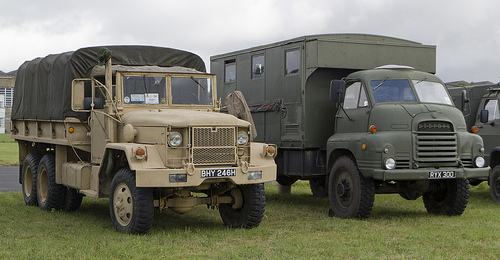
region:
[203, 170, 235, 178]
black and white licence plate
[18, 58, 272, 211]
tan and green army truck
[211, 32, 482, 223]
green metal army truck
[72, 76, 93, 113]
rear view truck mirror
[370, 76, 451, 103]
glass windshield on truck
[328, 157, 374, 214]
black rubber truck tire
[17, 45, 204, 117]
green tarp on truck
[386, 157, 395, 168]
round headlight on truck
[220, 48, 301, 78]
windows on side of truck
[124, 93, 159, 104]
papers in truck window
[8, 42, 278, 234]
large tan vehicle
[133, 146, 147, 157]
orange light on the front of a tan truck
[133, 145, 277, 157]
two orange lights on a tan vehicle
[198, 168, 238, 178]
black and white license plate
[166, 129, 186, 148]
round white light on the front of a tan vehicle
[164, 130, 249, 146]
two white headlights on a tan vehicle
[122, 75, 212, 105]
windshield of a tan truck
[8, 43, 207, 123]
black material covering the back of a truck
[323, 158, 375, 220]
large black wheel on a truck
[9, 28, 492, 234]
two trucks in a grassy area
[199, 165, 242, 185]
a black and white license plate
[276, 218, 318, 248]
green grass on the ground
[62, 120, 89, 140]
an orange rounded caution light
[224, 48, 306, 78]
windows in the side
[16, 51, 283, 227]
a large beige army truck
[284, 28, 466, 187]
an old fashioned green convoy truck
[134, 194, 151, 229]
thick black tread on a tire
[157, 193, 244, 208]
the beige axle of the truck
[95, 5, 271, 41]
thick white clouds in the sky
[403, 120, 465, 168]
the front grille on a truck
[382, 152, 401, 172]
a headlight of the truck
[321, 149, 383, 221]
the wheel of the truck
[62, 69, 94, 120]
a side view mirror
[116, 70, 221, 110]
the windshield of the truck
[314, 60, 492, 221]
the cabin of the truck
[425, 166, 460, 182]
a black license plate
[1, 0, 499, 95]
a cloudy gray sky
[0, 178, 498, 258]
a grassy green field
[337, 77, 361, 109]
the window of a truck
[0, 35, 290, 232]
a tan and black truck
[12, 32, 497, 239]
Army trucks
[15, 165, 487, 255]
Trucks parked on grass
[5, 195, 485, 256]
The green grass tells us it's summer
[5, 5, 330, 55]
Clouds in the sky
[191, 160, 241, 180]
License plate BHY 246H on tan truck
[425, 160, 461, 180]
License plate RTX 300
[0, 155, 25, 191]
Road behind trucks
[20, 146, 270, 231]
Tan truck has five visible tires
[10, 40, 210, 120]
Canvas covering over back of truck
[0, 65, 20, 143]
Stone building in background